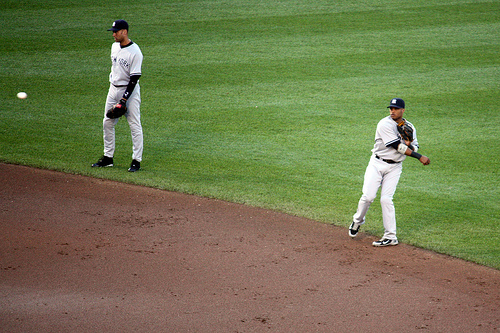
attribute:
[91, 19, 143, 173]
man — standing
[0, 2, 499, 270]
grass — here, green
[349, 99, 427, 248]
man — throwing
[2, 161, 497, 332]
dirt — here, brown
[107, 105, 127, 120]
glove — black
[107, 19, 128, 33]
cap — blue, black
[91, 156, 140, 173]
shoes — black, here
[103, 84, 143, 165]
pants — white, here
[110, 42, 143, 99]
shirt — black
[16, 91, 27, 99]
baseball — here, moving, white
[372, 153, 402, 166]
belt — here, white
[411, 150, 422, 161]
band — black